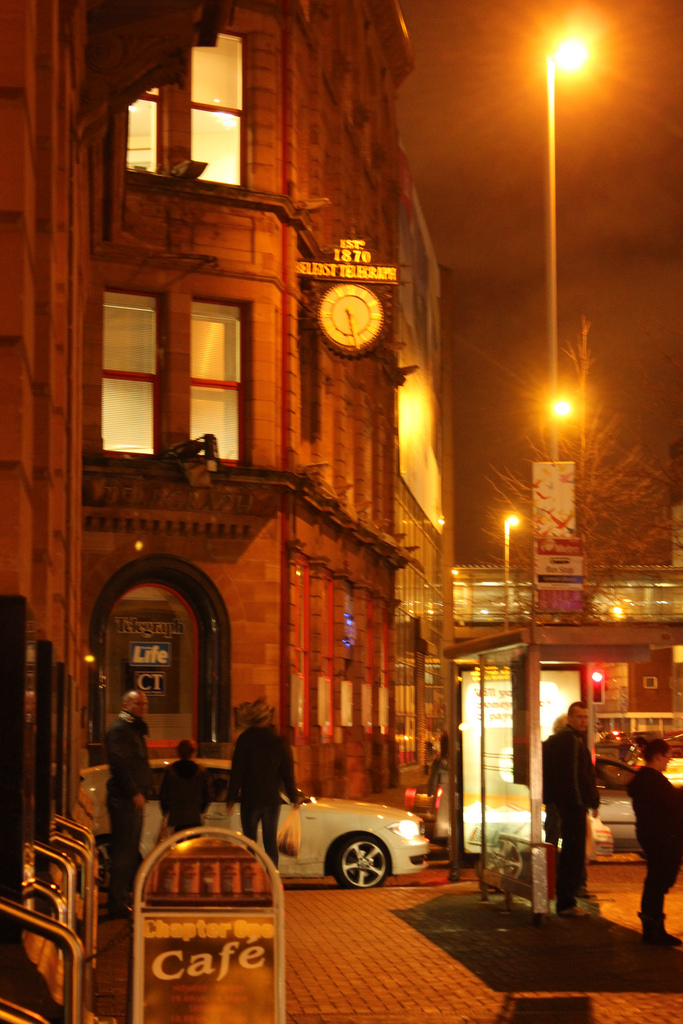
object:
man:
[228, 697, 300, 878]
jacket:
[226, 727, 298, 805]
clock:
[319, 282, 383, 349]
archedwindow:
[88, 551, 232, 744]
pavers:
[78, 867, 683, 1023]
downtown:
[1, 2, 677, 1024]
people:
[103, 691, 683, 946]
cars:
[94, 757, 427, 888]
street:
[74, 727, 683, 891]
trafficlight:
[591, 670, 603, 683]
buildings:
[0, 0, 459, 797]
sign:
[134, 825, 285, 1023]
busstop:
[442, 613, 591, 912]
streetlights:
[544, 391, 578, 424]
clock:
[313, 282, 392, 359]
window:
[190, 32, 245, 111]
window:
[126, 99, 158, 172]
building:
[67, 0, 451, 805]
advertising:
[130, 641, 173, 697]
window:
[96, 580, 198, 744]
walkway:
[278, 864, 525, 1024]